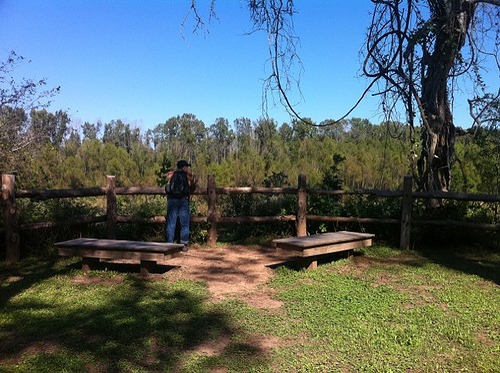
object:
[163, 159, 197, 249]
woman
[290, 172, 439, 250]
donut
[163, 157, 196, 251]
man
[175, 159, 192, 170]
hat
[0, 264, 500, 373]
ground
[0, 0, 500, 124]
blue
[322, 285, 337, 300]
green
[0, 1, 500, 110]
clouds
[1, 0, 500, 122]
clouds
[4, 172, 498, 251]
fence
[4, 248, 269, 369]
shadows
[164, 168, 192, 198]
backpack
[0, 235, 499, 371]
grass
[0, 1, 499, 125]
sky